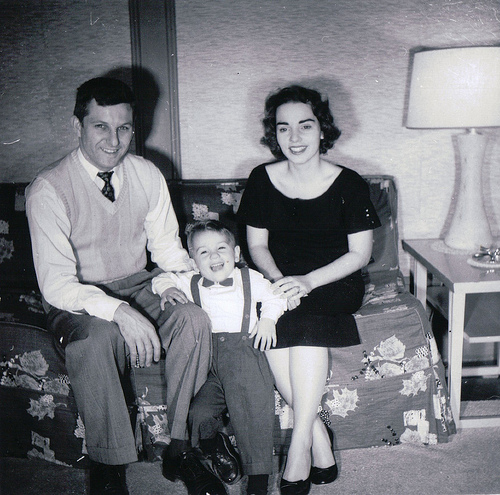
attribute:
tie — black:
[97, 171, 117, 200]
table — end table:
[386, 222, 495, 390]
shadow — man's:
[110, 65, 178, 177]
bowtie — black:
[191, 271, 241, 297]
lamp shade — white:
[402, 45, 498, 130]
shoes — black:
[83, 442, 254, 492]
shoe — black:
[283, 478, 310, 492]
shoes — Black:
[267, 414, 344, 492]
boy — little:
[151, 225, 288, 493]